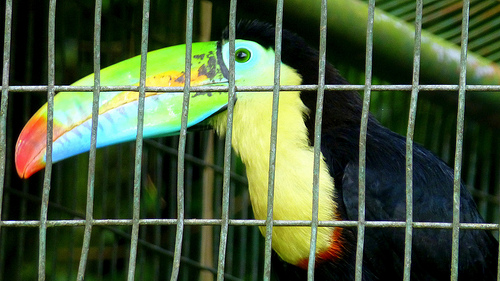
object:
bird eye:
[231, 47, 248, 62]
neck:
[219, 40, 336, 245]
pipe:
[305, 1, 491, 127]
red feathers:
[275, 214, 350, 272]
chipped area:
[195, 45, 231, 92]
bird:
[14, 20, 498, 279]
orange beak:
[15, 113, 46, 180]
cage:
[0, 0, 500, 279]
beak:
[12, 42, 224, 180]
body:
[223, 37, 494, 280]